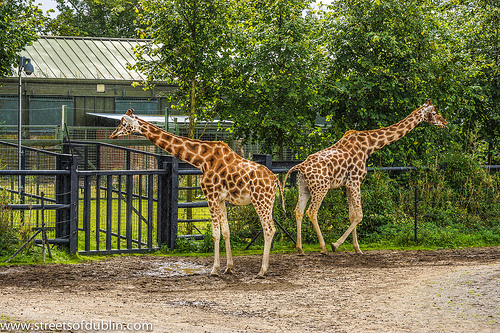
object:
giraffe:
[283, 96, 449, 256]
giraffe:
[108, 107, 285, 276]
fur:
[204, 168, 232, 181]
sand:
[216, 287, 381, 323]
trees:
[206, 29, 498, 189]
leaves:
[425, 22, 440, 38]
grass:
[425, 213, 495, 248]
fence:
[3, 166, 498, 261]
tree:
[162, 5, 213, 164]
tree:
[254, 0, 314, 173]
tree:
[301, 0, 470, 176]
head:
[104, 109, 143, 138]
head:
[423, 98, 445, 127]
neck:
[376, 108, 426, 147]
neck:
[138, 119, 209, 163]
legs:
[250, 201, 277, 278]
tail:
[281, 165, 299, 208]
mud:
[141, 258, 214, 280]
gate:
[77, 168, 171, 252]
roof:
[0, 37, 243, 79]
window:
[113, 98, 163, 120]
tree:
[128, 0, 260, 232]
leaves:
[177, 19, 197, 40]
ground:
[0, 247, 496, 331]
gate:
[3, 136, 498, 254]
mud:
[41, 261, 94, 287]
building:
[1, 34, 324, 182]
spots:
[332, 166, 342, 177]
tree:
[124, 0, 250, 233]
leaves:
[188, 43, 208, 58]